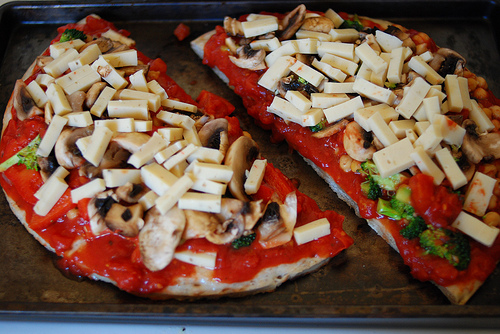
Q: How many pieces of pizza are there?
A: Two.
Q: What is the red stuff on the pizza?
A: Sauce.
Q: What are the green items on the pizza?
A: Broccoli.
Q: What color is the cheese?
A: White.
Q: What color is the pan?
A: Brown.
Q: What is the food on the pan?
A: Pizza.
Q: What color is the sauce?
A: Red.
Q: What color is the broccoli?
A: Green.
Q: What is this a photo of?
A: Food.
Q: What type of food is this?
A: Pizza.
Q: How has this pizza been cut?
A: In half.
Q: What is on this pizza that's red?
A: Tomato sauce.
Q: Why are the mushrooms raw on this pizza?
A: The pizza hasn't been cooked yet.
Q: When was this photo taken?
A: Before cooking a pizza.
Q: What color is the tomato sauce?
A: Red.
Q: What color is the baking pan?
A: Brown.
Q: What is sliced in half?
A: A pizza pie.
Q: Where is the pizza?
A: On a pan.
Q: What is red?
A: Tomato sauce.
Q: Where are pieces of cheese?
A: On the pizza.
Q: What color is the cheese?
A: White.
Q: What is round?
A: The pizza.